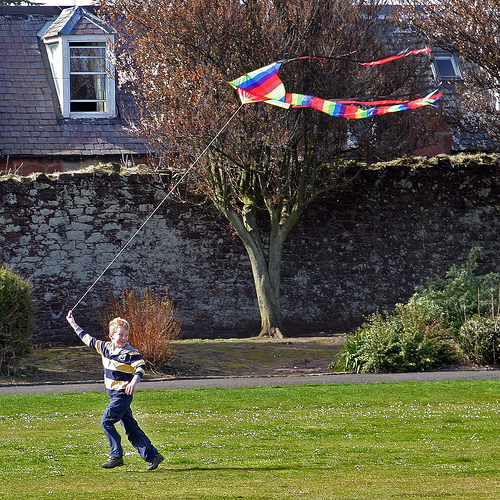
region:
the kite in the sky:
[227, 47, 448, 117]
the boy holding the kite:
[64, 308, 164, 471]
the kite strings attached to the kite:
[67, 86, 263, 318]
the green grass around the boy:
[0, 378, 499, 498]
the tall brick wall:
[0, 152, 498, 344]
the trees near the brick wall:
[93, 2, 496, 337]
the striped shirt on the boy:
[68, 316, 145, 398]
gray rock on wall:
[71, 192, 92, 211]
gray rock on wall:
[47, 210, 72, 227]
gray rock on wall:
[38, 228, 62, 242]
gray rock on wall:
[62, 225, 98, 245]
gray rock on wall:
[113, 225, 134, 245]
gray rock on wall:
[68, 247, 96, 268]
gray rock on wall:
[32, 262, 61, 284]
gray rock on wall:
[107, 275, 132, 290]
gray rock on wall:
[0, 215, 20, 238]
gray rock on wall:
[32, 175, 60, 194]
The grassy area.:
[5, 385, 496, 492]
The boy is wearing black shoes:
[101, 455, 173, 472]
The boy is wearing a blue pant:
[94, 392, 161, 457]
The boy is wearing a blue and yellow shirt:
[46, 326, 166, 398]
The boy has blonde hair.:
[98, 318, 131, 335]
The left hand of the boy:
[57, 312, 104, 349]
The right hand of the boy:
[125, 350, 149, 392]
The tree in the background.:
[121, 49, 415, 334]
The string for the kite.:
[62, 105, 272, 317]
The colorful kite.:
[229, 47, 455, 113]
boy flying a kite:
[62, 45, 444, 472]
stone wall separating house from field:
[1, 153, 495, 346]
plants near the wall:
[1, 247, 498, 378]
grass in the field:
[2, 374, 498, 499]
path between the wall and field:
[0, 367, 498, 397]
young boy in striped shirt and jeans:
[64, 314, 164, 472]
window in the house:
[38, 4, 118, 120]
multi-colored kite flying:
[227, 44, 444, 119]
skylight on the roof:
[428, 51, 465, 83]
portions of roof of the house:
[1, 3, 153, 157]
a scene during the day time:
[12, 9, 499, 490]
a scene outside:
[2, 8, 499, 496]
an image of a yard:
[9, 5, 497, 499]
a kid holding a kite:
[43, 16, 474, 471]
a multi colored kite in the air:
[206, 33, 470, 155]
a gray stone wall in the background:
[0, 141, 497, 371]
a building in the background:
[3, 5, 497, 185]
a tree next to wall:
[110, 0, 432, 338]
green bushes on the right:
[333, 235, 498, 389]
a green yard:
[10, 373, 487, 495]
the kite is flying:
[220, 55, 477, 182]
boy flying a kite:
[37, 246, 188, 478]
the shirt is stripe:
[58, 313, 173, 424]